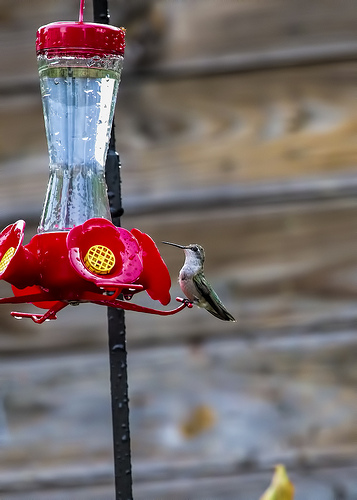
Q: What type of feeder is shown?
A: Humingbird feeder.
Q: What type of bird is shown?
A: A hummingbird.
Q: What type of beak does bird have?
A: Long needlelike beak.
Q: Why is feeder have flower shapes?
A: To attract hummingbirds.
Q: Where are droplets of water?
A: On hummingbird feeder.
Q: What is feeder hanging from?
A: A pole.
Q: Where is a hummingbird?
A: Perched on feeder.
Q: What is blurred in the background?
A: Wooden boards.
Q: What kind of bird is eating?
A: Hummingbird.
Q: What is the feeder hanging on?
A: Pole.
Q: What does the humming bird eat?
A: Sugar water.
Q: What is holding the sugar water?
A: Hummingbird feeder.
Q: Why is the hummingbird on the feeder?
A: To eat.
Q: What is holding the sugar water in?
A: Clear tube.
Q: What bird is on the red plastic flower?
A: A humming bird.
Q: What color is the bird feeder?
A: Red.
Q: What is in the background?
A: A fence.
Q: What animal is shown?
A: A bird.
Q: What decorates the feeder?
A: Flowers.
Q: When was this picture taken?
A: Daytime.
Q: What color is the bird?
A: Grey.